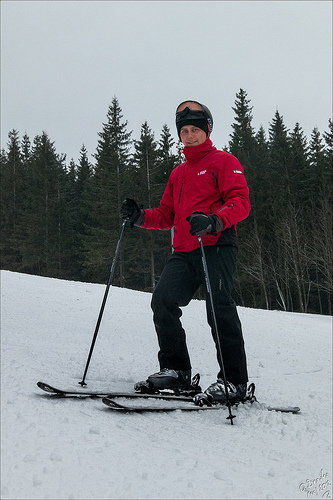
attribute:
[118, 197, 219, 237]
gloves — black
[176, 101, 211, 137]
hat — brown and black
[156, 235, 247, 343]
pants — black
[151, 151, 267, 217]
jacket — red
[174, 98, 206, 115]
goggles — orange, a pair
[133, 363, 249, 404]
shoes — ski, pair, black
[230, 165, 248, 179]
logo — white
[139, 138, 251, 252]
jacket — womans, red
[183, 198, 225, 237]
logo — white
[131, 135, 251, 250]
jacket — red, black, ski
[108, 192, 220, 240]
gloves — ski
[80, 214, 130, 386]
stick — ski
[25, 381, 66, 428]
logo — white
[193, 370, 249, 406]
boot — ski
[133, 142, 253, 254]
jacket — women's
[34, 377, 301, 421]
skies — women's